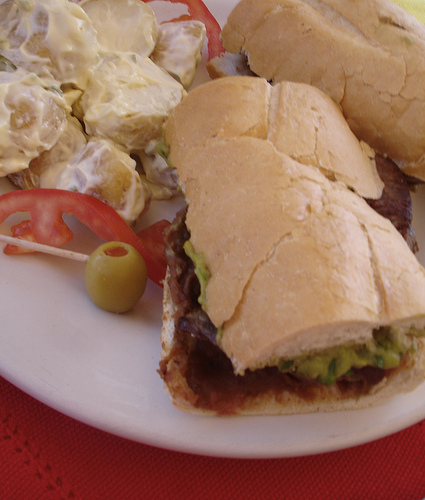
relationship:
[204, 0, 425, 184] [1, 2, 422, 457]
food on plate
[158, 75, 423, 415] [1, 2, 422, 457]
food on plate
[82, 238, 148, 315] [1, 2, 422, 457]
food on plate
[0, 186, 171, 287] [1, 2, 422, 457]
food on plate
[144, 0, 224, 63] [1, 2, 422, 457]
food on plate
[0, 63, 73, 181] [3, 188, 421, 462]
food on plate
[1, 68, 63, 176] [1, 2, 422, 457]
food on plate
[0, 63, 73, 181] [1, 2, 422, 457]
food on plate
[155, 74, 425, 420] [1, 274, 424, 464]
food on plate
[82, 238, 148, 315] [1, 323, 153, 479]
food on plate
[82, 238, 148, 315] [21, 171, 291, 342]
food on plate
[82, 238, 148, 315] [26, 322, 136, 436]
food rear plate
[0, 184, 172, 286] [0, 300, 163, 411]
food on plate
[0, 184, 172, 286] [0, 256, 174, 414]
food on plate